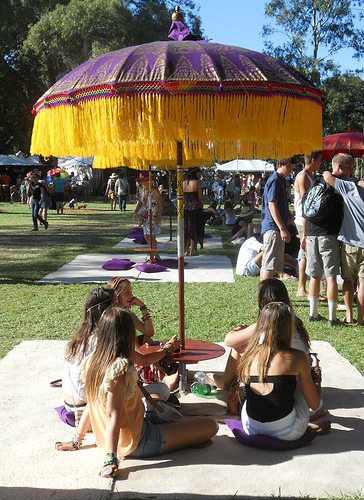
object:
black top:
[246, 375, 298, 423]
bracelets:
[72, 437, 82, 445]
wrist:
[73, 431, 85, 446]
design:
[304, 183, 324, 218]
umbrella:
[30, 3, 324, 392]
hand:
[166, 333, 183, 351]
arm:
[130, 308, 154, 337]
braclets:
[141, 312, 152, 321]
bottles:
[193, 371, 213, 385]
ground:
[0, 195, 364, 498]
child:
[68, 195, 77, 209]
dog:
[76, 201, 87, 209]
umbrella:
[215, 159, 274, 173]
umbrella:
[135, 162, 218, 241]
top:
[81, 351, 145, 459]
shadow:
[111, 370, 364, 479]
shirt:
[300, 171, 350, 234]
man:
[294, 151, 322, 297]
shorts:
[261, 229, 285, 272]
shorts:
[244, 258, 261, 276]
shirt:
[236, 236, 263, 275]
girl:
[55, 303, 219, 478]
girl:
[62, 287, 170, 412]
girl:
[205, 277, 312, 408]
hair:
[233, 300, 294, 387]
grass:
[3, 198, 354, 494]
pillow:
[102, 258, 136, 270]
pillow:
[134, 264, 168, 273]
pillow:
[155, 258, 188, 269]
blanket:
[34, 253, 234, 284]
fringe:
[30, 91, 323, 171]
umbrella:
[317, 123, 364, 159]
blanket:
[0, 339, 363, 498]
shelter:
[214, 156, 275, 172]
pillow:
[53, 405, 74, 427]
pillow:
[223, 418, 317, 450]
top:
[257, 323, 308, 355]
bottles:
[198, 384, 217, 395]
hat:
[109, 173, 119, 179]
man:
[300, 152, 353, 326]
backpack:
[298, 177, 333, 225]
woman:
[134, 171, 164, 262]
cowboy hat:
[135, 171, 155, 182]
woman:
[107, 277, 154, 345]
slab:
[0, 339, 364, 498]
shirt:
[244, 374, 297, 423]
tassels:
[29, 90, 323, 171]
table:
[138, 338, 225, 364]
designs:
[165, 56, 201, 82]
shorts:
[127, 413, 166, 458]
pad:
[0, 339, 364, 497]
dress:
[141, 186, 162, 235]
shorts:
[305, 236, 341, 277]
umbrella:
[92, 119, 214, 241]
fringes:
[92, 146, 214, 168]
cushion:
[102, 258, 137, 270]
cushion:
[134, 264, 168, 273]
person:
[105, 173, 119, 210]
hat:
[118, 171, 125, 178]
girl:
[235, 301, 322, 442]